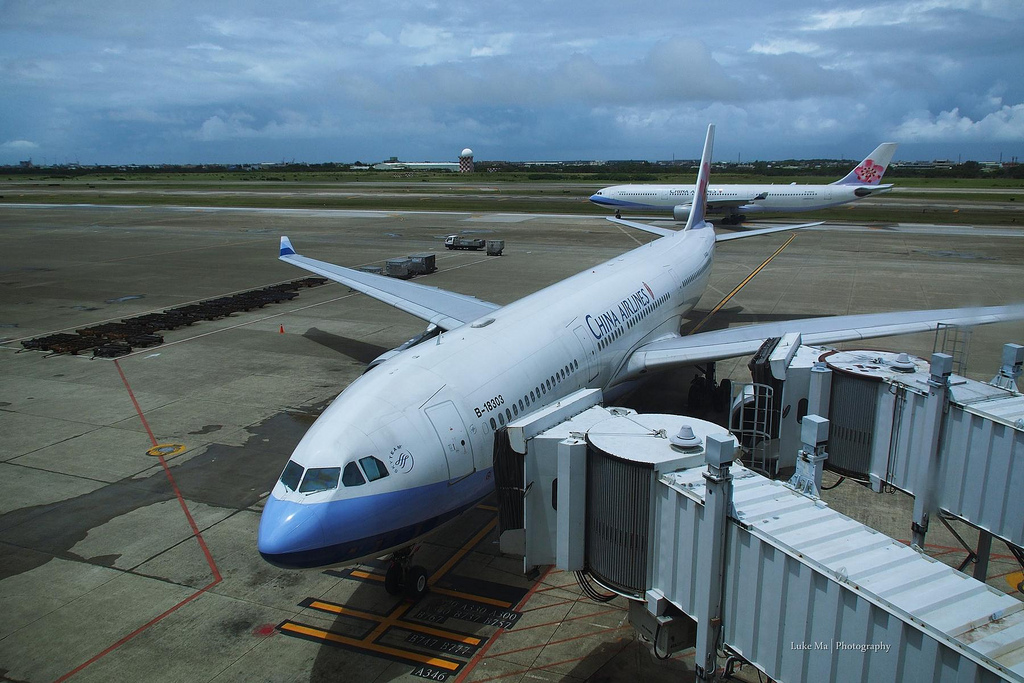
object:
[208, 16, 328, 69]
cloud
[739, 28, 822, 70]
cloud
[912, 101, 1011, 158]
cloud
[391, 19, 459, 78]
cloud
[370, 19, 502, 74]
cloud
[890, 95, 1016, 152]
cloud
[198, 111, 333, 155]
cloud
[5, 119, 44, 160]
cloud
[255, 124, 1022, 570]
airplane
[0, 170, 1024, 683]
ground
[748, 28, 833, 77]
cloud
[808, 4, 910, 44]
white cloud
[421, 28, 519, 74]
white cloud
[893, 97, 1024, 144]
white cloud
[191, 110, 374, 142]
white cloud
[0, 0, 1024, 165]
blue sky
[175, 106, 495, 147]
clouds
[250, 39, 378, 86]
clouds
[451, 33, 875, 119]
clodus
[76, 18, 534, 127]
cloud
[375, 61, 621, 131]
cloud